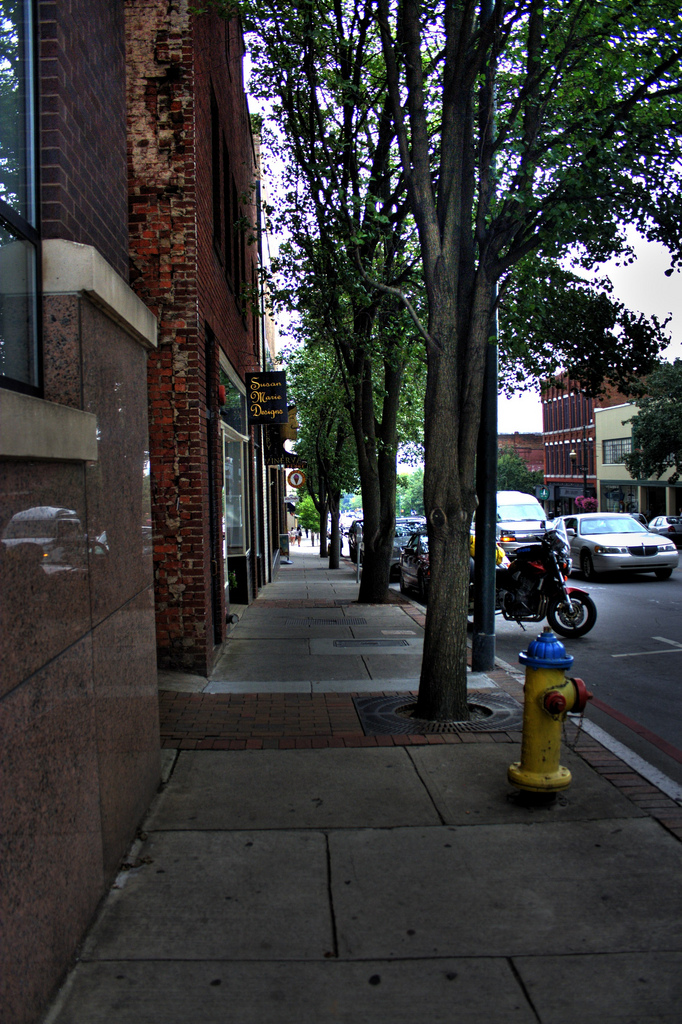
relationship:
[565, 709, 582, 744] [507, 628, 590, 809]
chain on front of fire hydrant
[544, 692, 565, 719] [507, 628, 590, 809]
lug on side of fire hydrant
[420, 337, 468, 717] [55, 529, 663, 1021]
tree trunk on sidewalk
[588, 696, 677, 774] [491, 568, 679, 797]
line drawn on street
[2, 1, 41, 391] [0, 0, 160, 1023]
window in front of building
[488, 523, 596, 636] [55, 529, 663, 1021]
motorcycle parked next to sidewalk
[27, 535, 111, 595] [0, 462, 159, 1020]
car reflection on wall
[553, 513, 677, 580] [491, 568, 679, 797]
car on street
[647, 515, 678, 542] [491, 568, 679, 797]
car on street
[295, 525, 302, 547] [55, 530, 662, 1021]
person on sidewalk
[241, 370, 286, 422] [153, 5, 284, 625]
sign on building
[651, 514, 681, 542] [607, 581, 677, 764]
vehicles parked along road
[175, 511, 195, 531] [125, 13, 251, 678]
brick on building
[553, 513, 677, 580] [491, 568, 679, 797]
car driving down street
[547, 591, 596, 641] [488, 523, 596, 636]
wheel on motorcycle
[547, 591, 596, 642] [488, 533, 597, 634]
wheel on bike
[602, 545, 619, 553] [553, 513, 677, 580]
headlight on car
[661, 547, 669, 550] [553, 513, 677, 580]
headlight on car